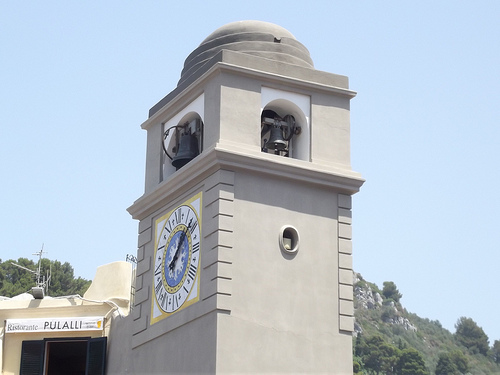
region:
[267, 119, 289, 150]
bell in tower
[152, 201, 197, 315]
clock face on tower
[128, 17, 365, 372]
a tower with bells and a clock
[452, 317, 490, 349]
a tree on the hill in the distance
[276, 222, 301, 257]
a round hole in the tower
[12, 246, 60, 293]
antenna on the building in the background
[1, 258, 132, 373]
building in the background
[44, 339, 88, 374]
open doorway on the building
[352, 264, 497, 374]
hill with vegetation in the backgroud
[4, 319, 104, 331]
sign on the building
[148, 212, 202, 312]
clock on the tower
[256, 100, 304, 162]
black bell on the tower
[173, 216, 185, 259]
black hands of the clock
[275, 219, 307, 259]
window in the tower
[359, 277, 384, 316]
rocky climate on the hill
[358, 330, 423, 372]
trees on the hill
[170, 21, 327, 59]
gray dome on top of the tower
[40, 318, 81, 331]
pulalli sign on building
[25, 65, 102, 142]
clear blue sunny sky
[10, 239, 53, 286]
antenna on top of the building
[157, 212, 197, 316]
clock in clock tower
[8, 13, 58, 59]
white clouds in blue sky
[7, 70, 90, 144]
white clouds in blue sky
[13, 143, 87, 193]
white clouds in blue sky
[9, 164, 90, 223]
white clouds in blue sky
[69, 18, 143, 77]
white clouds in blue sky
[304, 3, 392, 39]
white clouds in blue sky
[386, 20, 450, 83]
white clouds in blue sky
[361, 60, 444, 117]
white clouds in blue sky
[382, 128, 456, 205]
white clouds in blue sky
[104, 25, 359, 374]
light gray clock tower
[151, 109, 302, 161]
bell on clock tower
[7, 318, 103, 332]
white sign with black lettering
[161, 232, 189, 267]
black hands on clock face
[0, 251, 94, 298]
trees above store front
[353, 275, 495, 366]
tree covered hill on right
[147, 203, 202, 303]
roman numerals on clock face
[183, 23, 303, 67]
round top of clock tower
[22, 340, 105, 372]
windows of store front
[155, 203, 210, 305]
clock in tower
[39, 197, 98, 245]
white clouds in blue sky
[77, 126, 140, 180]
white clouds in blue sky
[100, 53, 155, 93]
white clouds in blue sky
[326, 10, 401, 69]
white clouds in blue sky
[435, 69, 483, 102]
white clouds in blue sky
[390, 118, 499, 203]
white clouds in blue sky